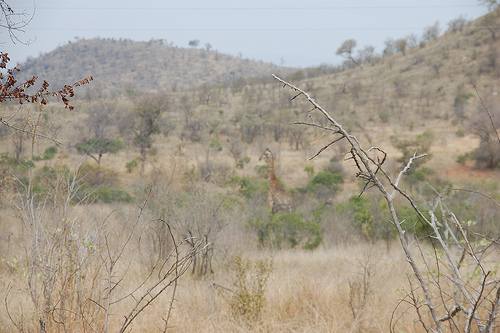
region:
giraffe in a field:
[256, 148, 299, 217]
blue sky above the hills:
[2, 3, 494, 67]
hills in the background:
[4, 9, 496, 108]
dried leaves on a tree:
[1, 50, 94, 118]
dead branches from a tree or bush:
[270, 65, 496, 329]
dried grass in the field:
[2, 248, 498, 331]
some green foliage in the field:
[3, 132, 457, 248]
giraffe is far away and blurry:
[257, 148, 295, 215]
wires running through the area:
[2, 2, 495, 34]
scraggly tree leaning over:
[333, 34, 363, 69]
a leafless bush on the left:
[6, 164, 195, 331]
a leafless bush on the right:
[267, 63, 499, 327]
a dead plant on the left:
[1, 163, 214, 331]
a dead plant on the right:
[262, 68, 497, 331]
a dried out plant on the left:
[0, 148, 196, 328]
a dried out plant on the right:
[270, 72, 495, 327]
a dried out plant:
[0, 161, 205, 331]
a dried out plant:
[265, 68, 496, 328]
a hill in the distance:
[2, 37, 296, 111]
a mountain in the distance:
[0, 28, 298, 115]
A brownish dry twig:
[5, 80, 74, 105]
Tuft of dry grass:
[188, 303, 210, 331]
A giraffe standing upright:
[255, 147, 291, 211]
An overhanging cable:
[225, 5, 274, 10]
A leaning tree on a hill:
[334, 38, 363, 70]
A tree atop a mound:
[188, 39, 201, 49]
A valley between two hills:
[174, 85, 204, 91]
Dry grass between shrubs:
[183, 100, 227, 112]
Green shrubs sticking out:
[263, 217, 310, 246]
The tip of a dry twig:
[270, 68, 285, 85]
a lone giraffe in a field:
[251, 140, 307, 220]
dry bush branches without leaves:
[262, 65, 492, 324]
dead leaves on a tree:
[0, 52, 124, 119]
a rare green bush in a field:
[251, 205, 329, 254]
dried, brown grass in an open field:
[230, 253, 375, 324]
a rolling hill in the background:
[11, 20, 317, 120]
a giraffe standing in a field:
[249, 148, 302, 220]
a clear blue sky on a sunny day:
[207, 3, 330, 60]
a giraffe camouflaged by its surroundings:
[248, 146, 304, 226]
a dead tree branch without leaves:
[267, 70, 482, 325]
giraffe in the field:
[255, 140, 305, 225]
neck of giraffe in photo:
[268, 156, 273, 187]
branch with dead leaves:
[4, 50, 100, 112]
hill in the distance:
[11, 20, 296, 88]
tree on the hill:
[333, 32, 368, 74]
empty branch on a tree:
[272, 67, 489, 317]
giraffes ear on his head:
[265, 148, 270, 153]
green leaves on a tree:
[447, 84, 471, 116]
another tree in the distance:
[125, 97, 165, 167]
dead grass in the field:
[285, 266, 339, 330]